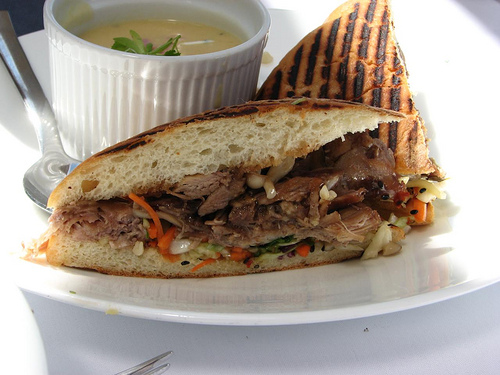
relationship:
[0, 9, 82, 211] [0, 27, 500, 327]
spoon on plate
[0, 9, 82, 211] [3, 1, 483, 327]
spoon on plate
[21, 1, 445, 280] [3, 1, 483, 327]
sandwiches on plate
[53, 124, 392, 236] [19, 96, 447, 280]
stuffing in sandwich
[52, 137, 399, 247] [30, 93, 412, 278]
meat inside sandwich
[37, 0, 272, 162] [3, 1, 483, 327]
bowl on plate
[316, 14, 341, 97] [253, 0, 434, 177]
line on bread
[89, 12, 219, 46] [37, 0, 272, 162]
soup inside bowl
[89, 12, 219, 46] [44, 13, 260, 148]
soup inside bowl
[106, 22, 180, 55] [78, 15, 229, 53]
leaf on top of soup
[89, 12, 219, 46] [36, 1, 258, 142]
soup inside bowl